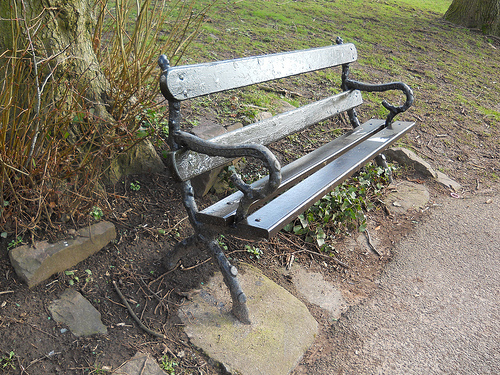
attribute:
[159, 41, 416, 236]
bench — park 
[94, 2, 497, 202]
grass — dead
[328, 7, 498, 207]
grass — patchy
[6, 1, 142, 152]
tree — gray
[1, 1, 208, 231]
grass — tall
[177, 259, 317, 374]
block — gray, cement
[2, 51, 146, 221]
trunk — tree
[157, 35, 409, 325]
bench — wood, metal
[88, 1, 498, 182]
grass — green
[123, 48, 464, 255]
bench — park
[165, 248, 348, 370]
pavers — cement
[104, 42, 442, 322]
bench — park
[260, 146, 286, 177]
metal end — metal 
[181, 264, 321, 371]
slabs — stone 